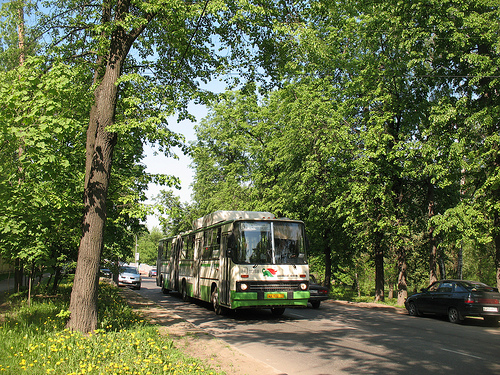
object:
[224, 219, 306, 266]
windshield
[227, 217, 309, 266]
front window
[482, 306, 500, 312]
license plate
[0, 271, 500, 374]
ground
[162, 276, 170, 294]
tire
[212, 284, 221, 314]
tire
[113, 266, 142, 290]
car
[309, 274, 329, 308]
black car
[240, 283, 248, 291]
headlight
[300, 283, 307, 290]
headlight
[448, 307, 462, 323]
wheel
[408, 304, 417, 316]
wheel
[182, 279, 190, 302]
wheel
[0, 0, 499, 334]
trees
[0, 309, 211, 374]
yellow flowers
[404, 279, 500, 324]
car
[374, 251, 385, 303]
stem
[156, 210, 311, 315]
bus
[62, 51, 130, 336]
trunk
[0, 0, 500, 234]
sky